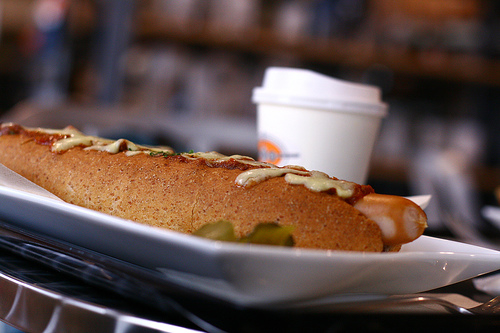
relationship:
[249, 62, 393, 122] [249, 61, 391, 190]
lid on cup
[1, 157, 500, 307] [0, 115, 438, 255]
plate holding pizza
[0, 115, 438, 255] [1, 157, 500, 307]
pizza on plate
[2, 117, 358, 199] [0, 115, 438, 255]
cheese on pizza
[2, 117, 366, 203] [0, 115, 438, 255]
cheese on pizza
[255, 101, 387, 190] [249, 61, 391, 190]
coffee in cup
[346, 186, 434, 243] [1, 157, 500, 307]
hot dog on plate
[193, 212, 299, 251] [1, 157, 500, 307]
pickles on plate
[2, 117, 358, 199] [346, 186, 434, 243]
cheese on hot dog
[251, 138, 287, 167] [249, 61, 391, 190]
logo on cup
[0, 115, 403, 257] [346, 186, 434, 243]
bread on hot dog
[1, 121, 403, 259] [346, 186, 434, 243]
coverings on hot dog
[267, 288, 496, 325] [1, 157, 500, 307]
silverware on plate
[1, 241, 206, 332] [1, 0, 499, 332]
countertop on bar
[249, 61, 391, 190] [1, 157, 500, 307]
cup beside plate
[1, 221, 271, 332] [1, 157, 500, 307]
plate under plate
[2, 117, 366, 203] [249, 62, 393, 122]
cheese on lid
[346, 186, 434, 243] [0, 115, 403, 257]
hot dog in bread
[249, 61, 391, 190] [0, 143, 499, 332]
cup on table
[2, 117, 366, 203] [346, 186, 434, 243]
cheese on hot dog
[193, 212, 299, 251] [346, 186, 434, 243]
pickles beside hot dog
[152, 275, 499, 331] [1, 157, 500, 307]
silverware beside plate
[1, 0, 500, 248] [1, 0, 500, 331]
background in restaurant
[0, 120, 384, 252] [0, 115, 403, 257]
crust on bread